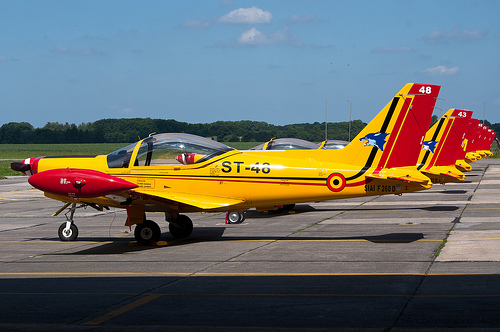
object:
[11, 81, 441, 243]
planes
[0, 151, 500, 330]
runway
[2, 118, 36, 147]
trees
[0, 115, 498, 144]
forest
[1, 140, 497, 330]
area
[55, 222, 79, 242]
wheel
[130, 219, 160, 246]
wheel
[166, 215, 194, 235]
wheel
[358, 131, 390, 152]
wolf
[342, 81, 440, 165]
tail wing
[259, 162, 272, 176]
number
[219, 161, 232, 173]
letter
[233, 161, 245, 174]
letter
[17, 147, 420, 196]
side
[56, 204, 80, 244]
landing gear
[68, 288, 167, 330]
line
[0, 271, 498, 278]
line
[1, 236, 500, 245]
line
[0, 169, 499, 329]
pavement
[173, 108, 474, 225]
plane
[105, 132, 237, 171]
window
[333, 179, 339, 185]
dot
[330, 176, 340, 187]
circle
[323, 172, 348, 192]
circle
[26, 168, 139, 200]
engine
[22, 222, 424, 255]
shadow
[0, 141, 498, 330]
ground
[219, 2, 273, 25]
cloud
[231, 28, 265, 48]
cloud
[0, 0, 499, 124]
sky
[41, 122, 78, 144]
trees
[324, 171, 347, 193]
design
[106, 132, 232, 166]
glass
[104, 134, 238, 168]
cockpit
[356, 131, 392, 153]
logo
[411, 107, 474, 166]
tail